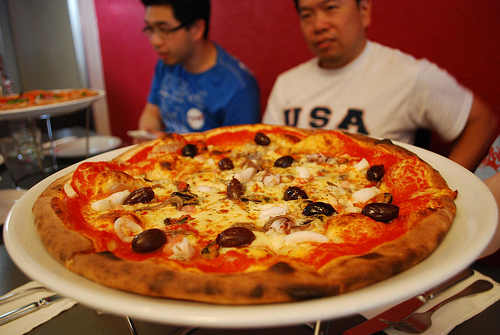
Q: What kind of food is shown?
A: Pizza.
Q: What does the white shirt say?
A: USA.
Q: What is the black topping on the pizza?
A: Olives.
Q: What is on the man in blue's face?
A: Glasses.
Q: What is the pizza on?
A: Plate.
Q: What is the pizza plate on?
A: Stand.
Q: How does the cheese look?
A: Melted.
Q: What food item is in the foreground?
A: Pizza.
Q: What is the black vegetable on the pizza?
A: Olive.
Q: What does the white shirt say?
A: USA.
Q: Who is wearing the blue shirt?
A: Man on left.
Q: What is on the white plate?
A: PIzza.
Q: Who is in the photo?
A: Two men.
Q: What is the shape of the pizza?
A: Round.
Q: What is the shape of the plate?
A: Round.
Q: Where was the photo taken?
A: REstaurant.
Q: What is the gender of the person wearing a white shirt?
A: Male.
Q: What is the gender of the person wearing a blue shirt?
A: Male.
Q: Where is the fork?
A: Beside the knife.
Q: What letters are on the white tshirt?
A: USA.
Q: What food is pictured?
A: Pizza.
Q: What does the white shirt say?
A: USA.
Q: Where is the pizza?
A: On a plate.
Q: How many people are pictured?
A: Two.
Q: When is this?
A: Dinner Time.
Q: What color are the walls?
A: Red.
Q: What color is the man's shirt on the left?
A: Blue.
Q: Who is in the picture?
A: Two men.